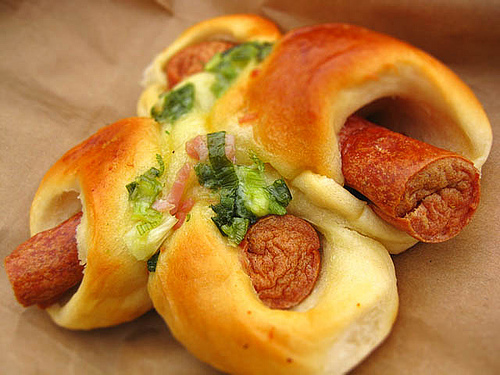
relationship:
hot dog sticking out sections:
[337, 114, 481, 243] [246, 21, 493, 255]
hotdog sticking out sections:
[240, 214, 321, 310] [151, 170, 398, 373]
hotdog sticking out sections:
[5, 209, 85, 310] [6, 116, 164, 332]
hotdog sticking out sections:
[165, 41, 235, 89] [138, 12, 290, 125]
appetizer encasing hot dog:
[3, 14, 495, 375] [332, 117, 475, 237]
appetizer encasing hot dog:
[3, 14, 495, 375] [243, 219, 325, 299]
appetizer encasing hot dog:
[3, 14, 495, 375] [7, 216, 87, 291]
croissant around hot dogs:
[135, 14, 282, 119] [161, 33, 237, 85]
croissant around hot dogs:
[205, 22, 494, 257] [331, 111, 480, 242]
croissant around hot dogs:
[28, 117, 170, 330] [2, 205, 85, 311]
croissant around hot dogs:
[147, 181, 401, 374] [233, 210, 324, 312]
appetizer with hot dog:
[3, 14, 495, 375] [337, 114, 481, 243]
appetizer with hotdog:
[3, 14, 495, 375] [240, 214, 321, 310]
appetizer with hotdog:
[3, 14, 495, 375] [5, 209, 85, 310]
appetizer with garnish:
[3, 14, 495, 375] [125, 131, 294, 273]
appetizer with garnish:
[3, 14, 495, 375] [203, 38, 274, 99]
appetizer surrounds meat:
[3, 14, 495, 375] [350, 134, 474, 233]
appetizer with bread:
[3, 13, 494, 373] [154, 275, 238, 339]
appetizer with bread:
[3, 13, 494, 373] [269, 57, 330, 133]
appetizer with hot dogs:
[3, 14, 495, 375] [4, 33, 479, 312]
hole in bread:
[343, 95, 465, 202] [213, 16, 495, 257]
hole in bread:
[121, 170, 165, 253] [21, 97, 178, 322]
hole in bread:
[27, 183, 104, 308] [24, 119, 181, 334]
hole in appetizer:
[220, 207, 322, 309] [3, 14, 495, 375]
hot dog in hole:
[332, 117, 475, 237] [337, 92, 429, 203]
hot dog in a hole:
[337, 114, 481, 243] [36, 189, 86, 327]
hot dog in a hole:
[337, 114, 481, 243] [335, 82, 477, 217]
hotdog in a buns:
[3, 200, 94, 311] [73, 88, 252, 373]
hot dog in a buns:
[337, 114, 481, 243] [241, 21, 492, 131]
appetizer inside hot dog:
[3, 14, 495, 375] [337, 114, 481, 243]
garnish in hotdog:
[125, 131, 294, 273] [240, 208, 325, 308]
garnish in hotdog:
[149, 78, 196, 121] [6, 200, 84, 311]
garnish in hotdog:
[206, 41, 273, 89] [6, 200, 84, 311]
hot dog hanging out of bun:
[337, 114, 481, 243] [28, 10, 488, 372]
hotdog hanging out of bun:
[165, 34, 236, 88] [28, 10, 488, 372]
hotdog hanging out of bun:
[214, 217, 323, 319] [28, 10, 488, 372]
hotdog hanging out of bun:
[5, 209, 85, 310] [28, 10, 488, 372]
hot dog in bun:
[337, 114, 481, 243] [244, 29, 494, 257]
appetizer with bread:
[3, 14, 495, 375] [237, 22, 399, 189]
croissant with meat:
[205, 22, 494, 257] [340, 101, 482, 247]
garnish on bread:
[103, 125, 291, 236] [141, 164, 402, 370]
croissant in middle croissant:
[136, 11, 403, 372] [238, 20, 498, 255]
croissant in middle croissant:
[238, 20, 498, 255] [26, 111, 178, 327]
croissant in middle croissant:
[26, 111, 178, 327] [146, 0, 284, 141]